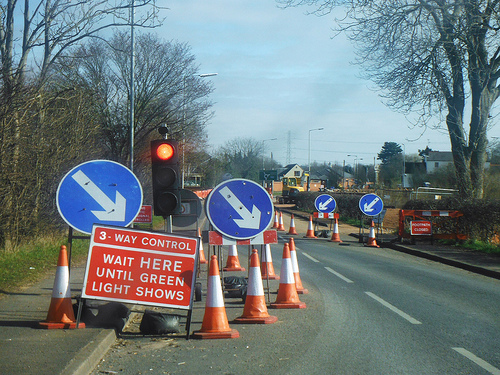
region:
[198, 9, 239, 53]
white clouds n blue sky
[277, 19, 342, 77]
white clouds n blue sky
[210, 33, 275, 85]
white clouds n blue sky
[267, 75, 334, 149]
white clouds n blue sky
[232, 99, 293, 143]
white clouds n blue sky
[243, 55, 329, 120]
white clouds n blue sky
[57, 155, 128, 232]
blue and white sign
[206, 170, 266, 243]
blue and white sign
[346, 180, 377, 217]
blue and white sign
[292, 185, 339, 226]
blue and white sign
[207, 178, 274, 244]
Blue and red sign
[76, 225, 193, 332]
A red sign with writing on it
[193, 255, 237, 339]
An orange and white cone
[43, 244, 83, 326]
Orange cone on a sidewalk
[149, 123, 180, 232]
Stop light on a pole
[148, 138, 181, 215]
Stop light on red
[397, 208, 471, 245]
Orange barricade on sidewalk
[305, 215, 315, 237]
Orange and white cone on the street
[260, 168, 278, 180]
Green traffic sign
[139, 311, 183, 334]
A black bag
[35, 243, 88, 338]
cone on a side walk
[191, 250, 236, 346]
cone on a street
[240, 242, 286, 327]
cone on a street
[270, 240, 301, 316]
cone on a street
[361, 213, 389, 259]
cone on a street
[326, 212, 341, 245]
cone on a street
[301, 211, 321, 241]
cone on a sreet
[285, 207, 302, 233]
cone on a street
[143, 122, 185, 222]
traffic light on a pole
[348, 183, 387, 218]
traffic sign on a street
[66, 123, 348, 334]
Signs on the road.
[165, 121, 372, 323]
Blue and white sign on the road.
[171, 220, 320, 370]
Orange and yellow cones.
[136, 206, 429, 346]
Orange and white cones.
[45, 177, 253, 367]
White and orange sign.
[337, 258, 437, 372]
White line on the road.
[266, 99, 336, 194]
House in the background.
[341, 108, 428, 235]
Tree by the house.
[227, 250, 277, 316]
White stripe on the cone.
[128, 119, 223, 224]
Stop light.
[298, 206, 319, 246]
cone on a street